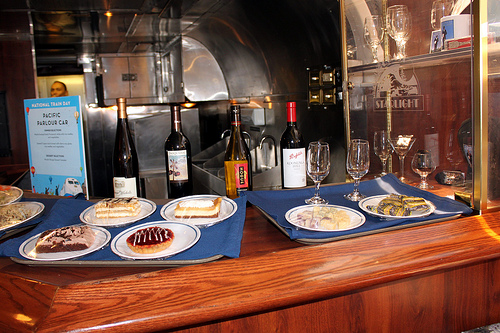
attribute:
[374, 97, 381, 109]
letter — white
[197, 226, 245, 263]
cloth — blue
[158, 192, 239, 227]
plate — white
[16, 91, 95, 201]
sign — blue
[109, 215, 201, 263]
plate — white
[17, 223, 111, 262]
plate — white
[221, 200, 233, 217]
plate — white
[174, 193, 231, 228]
dessert — white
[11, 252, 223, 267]
tray — silver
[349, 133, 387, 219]
glasses — clear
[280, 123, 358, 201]
glasses — clear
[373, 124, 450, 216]
glasses — clear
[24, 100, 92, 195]
menu — blue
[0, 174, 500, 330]
counter top — shiny, wooden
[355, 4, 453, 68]
glasses — empty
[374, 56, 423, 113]
logo — etched